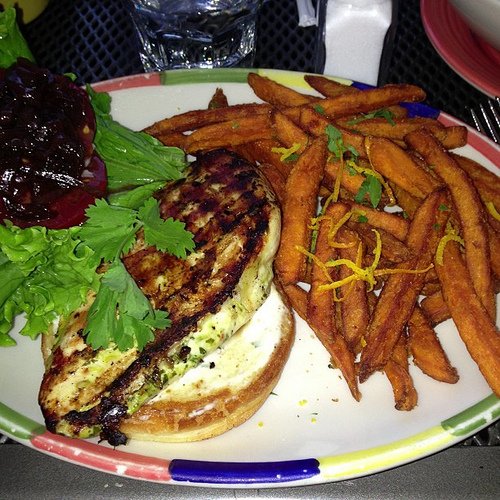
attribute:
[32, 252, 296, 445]
bun — white, grilled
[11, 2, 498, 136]
rubber mat — blue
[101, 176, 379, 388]
salmon — olive, oile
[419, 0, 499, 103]
plate — small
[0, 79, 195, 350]
arugula — green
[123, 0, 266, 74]
glass — clear, empty, drinking glass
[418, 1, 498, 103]
edge — pink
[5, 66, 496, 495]
plate — white, round